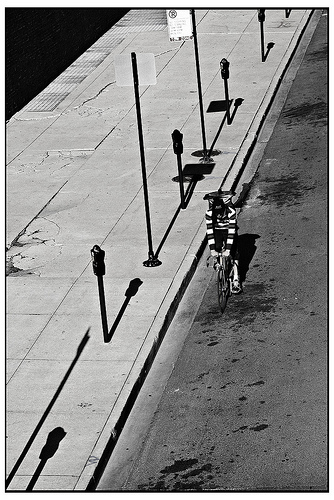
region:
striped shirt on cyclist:
[203, 206, 240, 249]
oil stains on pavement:
[134, 453, 218, 491]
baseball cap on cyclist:
[211, 198, 228, 215]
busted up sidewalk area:
[6, 212, 61, 276]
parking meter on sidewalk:
[88, 240, 119, 342]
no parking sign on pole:
[166, 7, 194, 43]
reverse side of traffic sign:
[112, 51, 158, 88]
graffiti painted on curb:
[84, 453, 99, 466]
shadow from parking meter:
[109, 276, 141, 339]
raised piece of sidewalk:
[25, 144, 94, 160]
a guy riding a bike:
[206, 188, 251, 302]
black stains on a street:
[164, 427, 237, 489]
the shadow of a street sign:
[40, 418, 68, 484]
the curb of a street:
[84, 440, 115, 468]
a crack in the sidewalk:
[27, 444, 59, 479]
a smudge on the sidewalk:
[73, 391, 92, 409]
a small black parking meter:
[76, 240, 124, 342]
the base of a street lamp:
[139, 253, 163, 273]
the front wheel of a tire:
[207, 261, 237, 304]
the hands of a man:
[199, 247, 234, 257]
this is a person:
[183, 180, 288, 336]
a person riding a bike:
[189, 174, 251, 319]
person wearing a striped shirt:
[187, 183, 243, 259]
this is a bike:
[201, 247, 241, 298]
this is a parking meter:
[89, 231, 123, 353]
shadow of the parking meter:
[104, 243, 149, 356]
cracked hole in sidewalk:
[0, 196, 76, 298]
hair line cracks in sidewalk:
[15, 132, 83, 194]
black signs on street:
[147, 441, 222, 488]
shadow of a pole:
[13, 315, 95, 498]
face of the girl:
[198, 190, 247, 227]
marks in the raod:
[151, 443, 219, 495]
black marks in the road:
[218, 386, 275, 454]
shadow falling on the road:
[23, 426, 106, 479]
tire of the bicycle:
[203, 275, 234, 315]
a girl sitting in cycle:
[193, 188, 261, 317]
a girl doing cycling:
[184, 191, 260, 309]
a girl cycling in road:
[191, 194, 265, 317]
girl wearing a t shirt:
[200, 215, 246, 249]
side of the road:
[112, 415, 130, 431]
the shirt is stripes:
[196, 212, 241, 261]